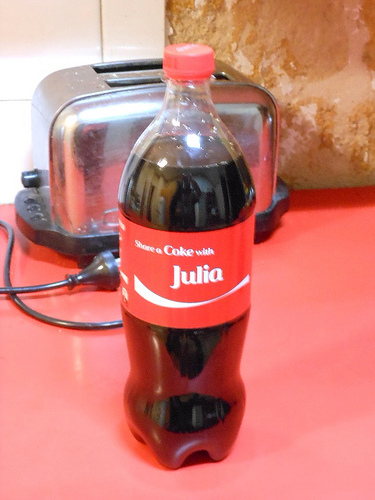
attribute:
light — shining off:
[182, 130, 203, 152]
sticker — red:
[116, 206, 256, 329]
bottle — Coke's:
[108, 36, 262, 473]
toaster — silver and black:
[2, 47, 296, 340]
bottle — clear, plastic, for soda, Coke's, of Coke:
[116, 44, 255, 467]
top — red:
[162, 35, 217, 84]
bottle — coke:
[64, 24, 297, 468]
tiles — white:
[2, 0, 170, 203]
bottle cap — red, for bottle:
[161, 40, 219, 78]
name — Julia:
[167, 262, 222, 288]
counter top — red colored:
[9, 211, 371, 265]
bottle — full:
[122, 40, 245, 465]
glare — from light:
[184, 133, 203, 149]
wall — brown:
[162, 12, 370, 158]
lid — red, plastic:
[158, 37, 219, 89]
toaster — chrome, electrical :
[14, 55, 290, 260]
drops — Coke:
[128, 87, 243, 168]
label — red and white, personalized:
[114, 218, 255, 331]